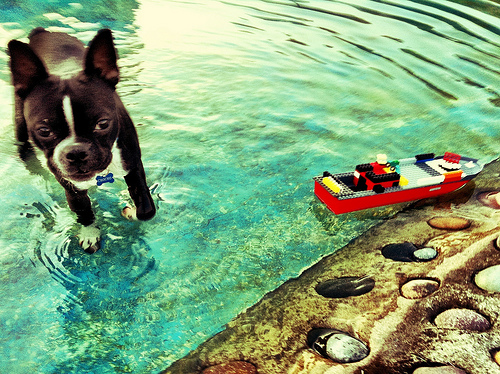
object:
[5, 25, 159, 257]
dog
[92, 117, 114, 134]
eye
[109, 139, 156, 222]
leg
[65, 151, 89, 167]
nose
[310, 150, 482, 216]
boat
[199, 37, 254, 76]
light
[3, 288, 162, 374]
water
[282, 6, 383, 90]
ripple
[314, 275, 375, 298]
rock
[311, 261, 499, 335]
land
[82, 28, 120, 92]
ear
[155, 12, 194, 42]
sun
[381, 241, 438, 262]
stone